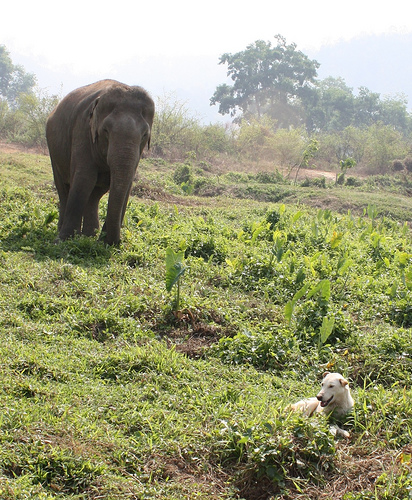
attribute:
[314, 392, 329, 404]
nose — black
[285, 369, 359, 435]
dog — white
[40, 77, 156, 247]
elephant — Gray 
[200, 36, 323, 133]
trees — hazy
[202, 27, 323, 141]
tree — large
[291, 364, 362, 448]
mouth — open, dog's 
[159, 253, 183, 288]
leaf — Large green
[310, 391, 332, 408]
nose — dog's , black 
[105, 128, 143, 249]
trunk — Gray 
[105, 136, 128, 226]
trunk — long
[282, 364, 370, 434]
dog — white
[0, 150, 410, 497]
grass — weedy, green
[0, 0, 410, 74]
sky — grey, overcast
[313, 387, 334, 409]
mouth — open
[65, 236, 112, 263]
weeds — Yellow 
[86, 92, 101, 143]
ears — elephant's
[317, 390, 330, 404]
nose — Black 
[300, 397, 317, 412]
fur — white